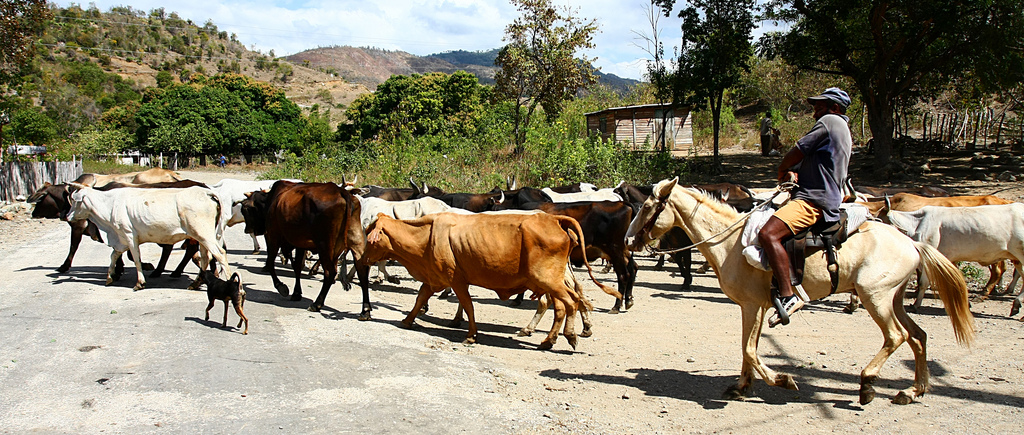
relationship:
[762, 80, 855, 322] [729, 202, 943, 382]
man riding horse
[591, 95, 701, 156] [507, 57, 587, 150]
shack behind tree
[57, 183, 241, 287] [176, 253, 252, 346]
cow next to dog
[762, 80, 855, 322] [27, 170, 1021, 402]
man herding cows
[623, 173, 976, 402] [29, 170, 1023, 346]
horse helping cow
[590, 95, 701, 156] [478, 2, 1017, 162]
shack surrounded by trees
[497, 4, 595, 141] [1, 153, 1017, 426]
tree in field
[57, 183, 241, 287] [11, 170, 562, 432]
cow walking down path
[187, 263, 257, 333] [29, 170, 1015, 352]
dog walking with cows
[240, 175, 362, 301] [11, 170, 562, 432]
cow walking down path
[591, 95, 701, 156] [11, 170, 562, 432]
shack on side path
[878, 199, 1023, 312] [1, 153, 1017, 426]
cow in field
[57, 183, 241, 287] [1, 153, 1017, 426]
cow in field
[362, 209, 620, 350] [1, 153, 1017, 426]
cow in field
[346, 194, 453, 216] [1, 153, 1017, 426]
cow in field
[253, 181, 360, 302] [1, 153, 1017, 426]
cow in field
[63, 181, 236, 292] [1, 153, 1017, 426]
cow in field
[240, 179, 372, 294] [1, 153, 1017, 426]
cow in field